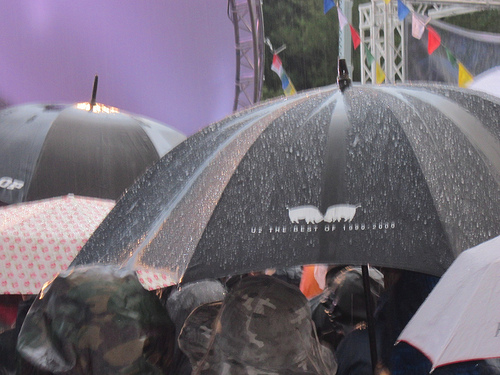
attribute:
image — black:
[270, 182, 397, 237]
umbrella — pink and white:
[114, 72, 495, 312]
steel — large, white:
[351, 0, 408, 81]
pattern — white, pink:
[52, 242, 62, 250]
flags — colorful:
[320, 2, 474, 86]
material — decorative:
[13, 261, 179, 373]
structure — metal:
[360, 6, 496, 88]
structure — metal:
[334, 0, 354, 83]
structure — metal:
[226, 2, 271, 113]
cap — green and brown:
[16, 263, 191, 373]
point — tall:
[333, 57, 351, 88]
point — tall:
[87, 74, 99, 106]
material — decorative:
[81, 42, 498, 340]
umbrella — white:
[75, 80, 496, 323]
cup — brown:
[231, 292, 308, 356]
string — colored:
[327, 0, 394, 82]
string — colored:
[264, 35, 299, 92]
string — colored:
[383, 0, 498, 93]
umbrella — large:
[59, 83, 483, 265]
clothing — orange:
[293, 266, 328, 301]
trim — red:
[399, 334, 479, 373]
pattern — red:
[9, 205, 71, 265]